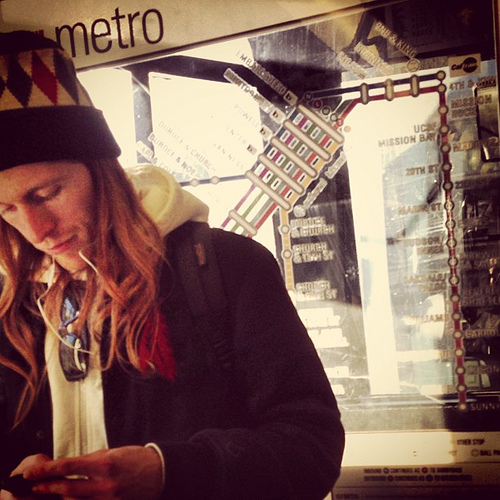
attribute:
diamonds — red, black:
[0, 43, 79, 103]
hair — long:
[2, 154, 179, 428]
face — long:
[0, 158, 95, 274]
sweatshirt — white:
[35, 261, 118, 455]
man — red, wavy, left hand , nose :
[5, 25, 355, 488]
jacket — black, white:
[4, 224, 353, 490]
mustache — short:
[31, 228, 76, 242]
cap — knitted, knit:
[0, 24, 125, 175]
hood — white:
[126, 164, 213, 233]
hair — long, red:
[136, 304, 176, 380]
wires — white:
[31, 250, 117, 364]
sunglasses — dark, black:
[55, 275, 95, 382]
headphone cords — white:
[31, 241, 116, 358]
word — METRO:
[52, 2, 171, 63]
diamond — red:
[27, 46, 63, 103]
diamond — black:
[4, 52, 33, 108]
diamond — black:
[50, 42, 80, 98]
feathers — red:
[130, 308, 183, 384]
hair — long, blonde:
[70, 155, 179, 378]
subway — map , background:
[1, 5, 484, 493]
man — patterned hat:
[5, 60, 374, 478]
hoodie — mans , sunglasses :
[114, 149, 206, 230]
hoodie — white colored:
[114, 160, 216, 251]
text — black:
[30, 0, 184, 58]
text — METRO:
[57, 5, 186, 69]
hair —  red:
[85, 179, 170, 361]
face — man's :
[3, 164, 108, 303]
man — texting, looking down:
[17, 51, 310, 478]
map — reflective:
[305, 90, 487, 414]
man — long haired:
[4, 44, 189, 364]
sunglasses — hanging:
[31, 284, 111, 367]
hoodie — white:
[58, 183, 243, 437]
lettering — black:
[51, 13, 231, 87]